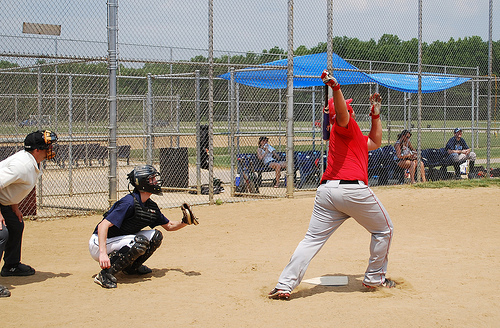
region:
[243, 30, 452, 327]
the batter is looking up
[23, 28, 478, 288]
people playing a baseball game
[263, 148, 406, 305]
standing at home plate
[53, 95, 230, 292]
the catcher is a woman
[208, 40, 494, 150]
the tarp is blue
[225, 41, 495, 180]
this is the dugout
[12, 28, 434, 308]
the catcher is ready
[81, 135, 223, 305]
the catcher has a blue shirt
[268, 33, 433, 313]
her hat is red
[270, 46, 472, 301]
her shirt is red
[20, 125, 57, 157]
black hat and face mask of umpire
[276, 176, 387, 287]
white pants of batter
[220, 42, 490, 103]
blue plastic shade protector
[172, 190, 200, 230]
catchers mit in left hand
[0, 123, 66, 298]
umpire bending over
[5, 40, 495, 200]
ballpark wire safety fence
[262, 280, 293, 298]
left shoe of batter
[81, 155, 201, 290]
catcher of baseball team bending down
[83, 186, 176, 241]
purple shirt of catcher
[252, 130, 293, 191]
woman sitting watching game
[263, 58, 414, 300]
a batter who just swong at the ball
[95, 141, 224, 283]
a catcher with a ball in his mitt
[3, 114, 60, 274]
a baseball umpire in white shirt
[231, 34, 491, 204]
a blue tarp over people watching game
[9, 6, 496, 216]
chain link fence all around the baseball field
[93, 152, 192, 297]
a catcher with all protective gear on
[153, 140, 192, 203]
a black barrel used for a trash can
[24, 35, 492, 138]
a line of green trees in the background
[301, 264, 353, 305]
home plate nice and cleaned off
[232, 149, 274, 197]
bats leaning against the fence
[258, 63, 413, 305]
player with twisted body and raised arms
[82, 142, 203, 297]
catcher crouched with elbow bent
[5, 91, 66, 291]
umpire leaning forward with hand on knee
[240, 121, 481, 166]
spectators seated and relaxed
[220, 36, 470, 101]
blue tarp hung as roofing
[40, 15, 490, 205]
tall metal fencing behind players and spectators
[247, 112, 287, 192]
person drinking from jug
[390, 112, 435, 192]
woman in sunglasses not watching game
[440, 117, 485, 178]
man in uniform watching game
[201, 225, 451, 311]
home base placed on brown ground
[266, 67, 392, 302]
Baseball batter seems to have lost bat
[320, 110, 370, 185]
Red shirt on baseball player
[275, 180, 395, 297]
Gray pants with red stripe on baseball player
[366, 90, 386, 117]
Red and white batting glove on player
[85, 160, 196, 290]
Catcher in squat in baseball game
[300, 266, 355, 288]
Home plate on baseball field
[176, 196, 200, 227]
Mitt in hand of baseball catcher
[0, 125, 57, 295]
Home plate umpire at baseball game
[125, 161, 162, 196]
Mask worn by baseball catcher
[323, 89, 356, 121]
Red helmet on baseball player